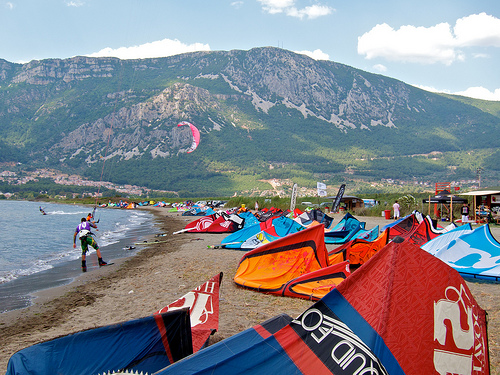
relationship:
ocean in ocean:
[0, 195, 160, 317] [1, 179, 161, 306]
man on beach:
[68, 216, 122, 276] [59, 186, 484, 352]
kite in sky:
[157, 101, 216, 175] [9, 3, 481, 83]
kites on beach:
[201, 198, 461, 370] [59, 186, 484, 352]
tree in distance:
[84, 131, 133, 184] [27, 59, 424, 201]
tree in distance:
[89, 150, 137, 184] [20, 110, 415, 206]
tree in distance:
[130, 176, 157, 197] [14, 70, 450, 202]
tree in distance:
[129, 136, 169, 161] [16, 58, 462, 190]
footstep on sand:
[62, 258, 112, 281] [35, 242, 171, 318]